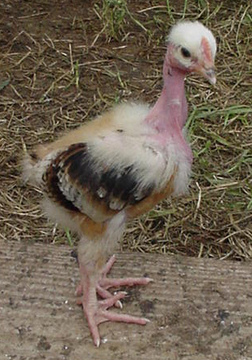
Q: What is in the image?
A: A baby bird.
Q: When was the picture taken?
A: Daytime.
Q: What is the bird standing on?
A: Wood.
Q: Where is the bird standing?
A: On a piece of wood.